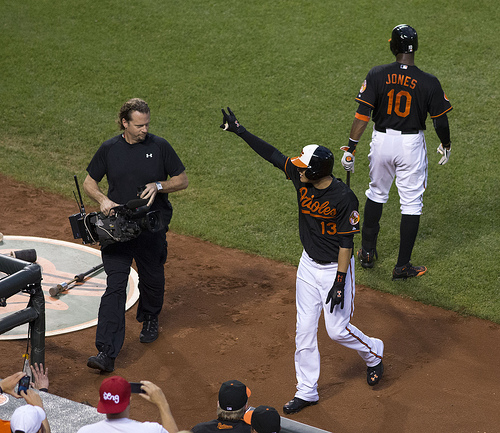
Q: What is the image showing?
A: It is showing a field.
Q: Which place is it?
A: It is a field.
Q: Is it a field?
A: Yes, it is a field.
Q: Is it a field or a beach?
A: It is a field.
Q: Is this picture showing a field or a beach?
A: It is showing a field.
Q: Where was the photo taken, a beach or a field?
A: It was taken at a field.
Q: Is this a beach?
A: No, it is a field.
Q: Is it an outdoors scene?
A: Yes, it is outdoors.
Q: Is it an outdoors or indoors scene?
A: It is outdoors.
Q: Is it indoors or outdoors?
A: It is outdoors.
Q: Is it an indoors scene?
A: No, it is outdoors.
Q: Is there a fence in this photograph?
A: No, there are no fences.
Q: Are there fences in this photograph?
A: No, there are no fences.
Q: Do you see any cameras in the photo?
A: Yes, there is a camera.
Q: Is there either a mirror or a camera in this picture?
A: Yes, there is a camera.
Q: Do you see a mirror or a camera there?
A: Yes, there is a camera.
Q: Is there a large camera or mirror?
A: Yes, there is a large camera.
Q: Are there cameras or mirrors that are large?
A: Yes, the camera is large.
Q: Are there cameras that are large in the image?
A: Yes, there is a large camera.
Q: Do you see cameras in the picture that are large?
A: Yes, there is a camera that is large.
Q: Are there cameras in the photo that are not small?
A: Yes, there is a large camera.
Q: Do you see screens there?
A: No, there are no screens.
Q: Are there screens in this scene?
A: No, there are no screens.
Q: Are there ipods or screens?
A: No, there are no screens or ipods.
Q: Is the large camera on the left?
A: Yes, the camera is on the left of the image.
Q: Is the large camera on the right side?
A: No, the camera is on the left of the image.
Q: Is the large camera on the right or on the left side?
A: The camera is on the left of the image.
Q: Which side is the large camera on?
A: The camera is on the left of the image.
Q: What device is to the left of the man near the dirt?
A: The device is a camera.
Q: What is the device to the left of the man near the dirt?
A: The device is a camera.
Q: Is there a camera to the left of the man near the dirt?
A: Yes, there is a camera to the left of the man.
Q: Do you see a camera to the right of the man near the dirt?
A: No, the camera is to the left of the man.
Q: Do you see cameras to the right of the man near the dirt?
A: No, the camera is to the left of the man.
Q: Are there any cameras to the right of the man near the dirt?
A: No, the camera is to the left of the man.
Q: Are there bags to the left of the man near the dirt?
A: No, there is a camera to the left of the man.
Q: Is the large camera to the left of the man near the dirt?
A: Yes, the camera is to the left of the man.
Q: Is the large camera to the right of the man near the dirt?
A: No, the camera is to the left of the man.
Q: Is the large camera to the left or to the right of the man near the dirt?
A: The camera is to the left of the man.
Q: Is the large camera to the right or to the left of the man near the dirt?
A: The camera is to the left of the man.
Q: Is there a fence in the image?
A: No, there are no fences.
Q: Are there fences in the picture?
A: No, there are no fences.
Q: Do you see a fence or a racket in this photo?
A: No, there are no fences or rackets.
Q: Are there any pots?
A: No, there are no pots.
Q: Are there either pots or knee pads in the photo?
A: No, there are no pots or knee pads.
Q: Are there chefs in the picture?
A: No, there are no chefs.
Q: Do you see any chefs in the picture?
A: No, there are no chefs.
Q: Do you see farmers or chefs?
A: No, there are no chefs or farmers.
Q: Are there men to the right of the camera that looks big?
A: Yes, there is a man to the right of the camera.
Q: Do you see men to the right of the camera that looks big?
A: Yes, there is a man to the right of the camera.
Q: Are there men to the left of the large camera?
A: No, the man is to the right of the camera.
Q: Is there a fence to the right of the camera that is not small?
A: No, there is a man to the right of the camera.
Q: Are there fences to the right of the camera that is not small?
A: No, there is a man to the right of the camera.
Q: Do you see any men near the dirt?
A: Yes, there is a man near the dirt.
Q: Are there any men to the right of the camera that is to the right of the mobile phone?
A: Yes, there is a man to the right of the camera.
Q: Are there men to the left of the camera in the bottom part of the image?
A: No, the man is to the right of the camera.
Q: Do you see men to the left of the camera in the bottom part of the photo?
A: No, the man is to the right of the camera.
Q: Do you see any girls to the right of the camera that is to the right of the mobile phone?
A: No, there is a man to the right of the camera.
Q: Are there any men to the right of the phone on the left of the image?
A: Yes, there is a man to the right of the phone.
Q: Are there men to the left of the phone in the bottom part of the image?
A: No, the man is to the right of the telephone.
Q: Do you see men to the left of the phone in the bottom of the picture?
A: No, the man is to the right of the telephone.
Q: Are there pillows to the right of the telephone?
A: No, there is a man to the right of the telephone.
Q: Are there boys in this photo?
A: No, there are no boys.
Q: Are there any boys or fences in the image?
A: No, there are no boys or fences.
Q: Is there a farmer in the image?
A: No, there are no farmers.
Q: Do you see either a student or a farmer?
A: No, there are no farmers or students.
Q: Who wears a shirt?
A: The man wears a shirt.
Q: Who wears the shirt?
A: The man wears a shirt.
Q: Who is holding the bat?
A: The man is holding the bat.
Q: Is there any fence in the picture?
A: No, there are no fences.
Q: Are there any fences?
A: No, there are no fences.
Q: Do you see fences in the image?
A: No, there are no fences.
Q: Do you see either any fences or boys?
A: No, there are no fences or boys.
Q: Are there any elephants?
A: Yes, there is an elephant.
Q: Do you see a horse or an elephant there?
A: Yes, there is an elephant.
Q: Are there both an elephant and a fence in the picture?
A: No, there is an elephant but no fences.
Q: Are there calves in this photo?
A: No, there are no calves.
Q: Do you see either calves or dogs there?
A: No, there are no calves or dogs.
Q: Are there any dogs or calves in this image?
A: No, there are no calves or dogs.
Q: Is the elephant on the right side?
A: Yes, the elephant is on the right of the image.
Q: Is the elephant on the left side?
A: No, the elephant is on the right of the image.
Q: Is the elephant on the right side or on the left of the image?
A: The elephant is on the right of the image.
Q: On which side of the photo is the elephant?
A: The elephant is on the right of the image.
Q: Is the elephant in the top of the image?
A: Yes, the elephant is in the top of the image.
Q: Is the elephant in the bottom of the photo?
A: No, the elephant is in the top of the image.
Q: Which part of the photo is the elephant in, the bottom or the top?
A: The elephant is in the top of the image.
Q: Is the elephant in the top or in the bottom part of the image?
A: The elephant is in the top of the image.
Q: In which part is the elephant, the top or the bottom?
A: The elephant is in the top of the image.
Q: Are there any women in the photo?
A: No, there are no women.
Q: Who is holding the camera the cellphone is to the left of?
A: The man is holding the camera.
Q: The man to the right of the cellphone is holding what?
A: The man is holding the camera.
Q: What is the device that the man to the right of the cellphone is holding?
A: The device is a camera.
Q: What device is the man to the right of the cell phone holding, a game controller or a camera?
A: The man is holding a camera.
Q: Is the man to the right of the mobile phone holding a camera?
A: Yes, the man is holding a camera.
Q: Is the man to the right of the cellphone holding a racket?
A: No, the man is holding a camera.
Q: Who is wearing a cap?
A: The man is wearing a cap.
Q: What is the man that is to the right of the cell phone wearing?
A: The man is wearing a cap.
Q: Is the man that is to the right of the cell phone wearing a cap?
A: Yes, the man is wearing a cap.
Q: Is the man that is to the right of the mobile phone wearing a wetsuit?
A: No, the man is wearing a cap.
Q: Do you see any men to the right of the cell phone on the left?
A: Yes, there is a man to the right of the mobile phone.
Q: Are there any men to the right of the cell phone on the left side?
A: Yes, there is a man to the right of the mobile phone.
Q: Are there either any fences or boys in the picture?
A: No, there are no fences or boys.